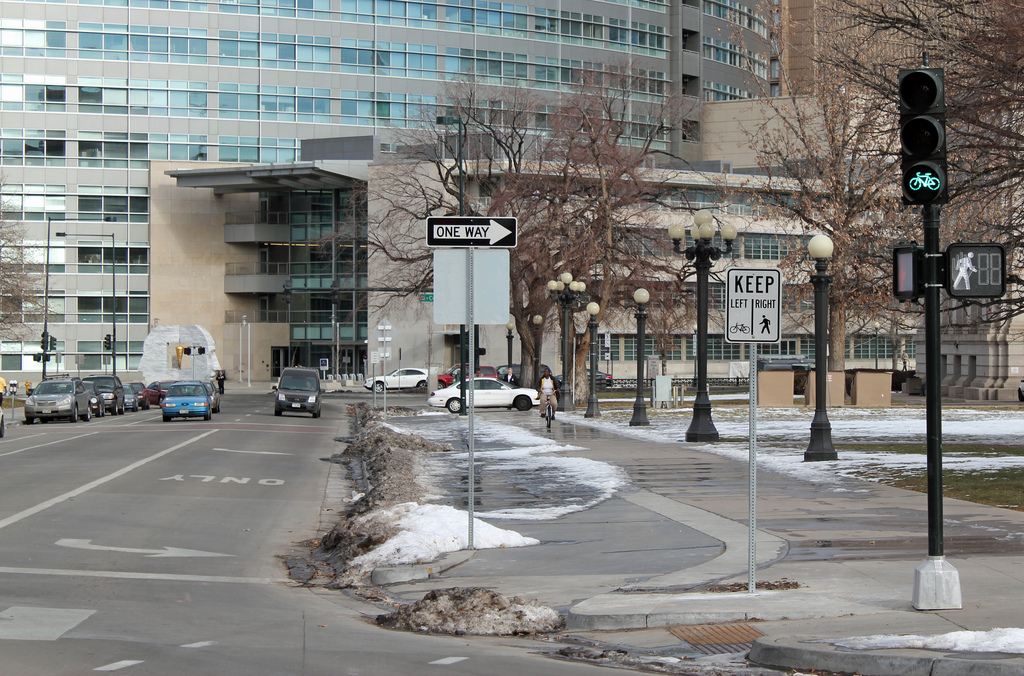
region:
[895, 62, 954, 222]
Stop sign attached to pole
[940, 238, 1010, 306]
Walk indicator sign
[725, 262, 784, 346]
White street sign with black lettering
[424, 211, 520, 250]
One way street sign attached to pole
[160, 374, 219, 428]
Blue car driving on road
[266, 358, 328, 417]
Black van in turn lane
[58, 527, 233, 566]
White painted arrow on road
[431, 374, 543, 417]
White car on road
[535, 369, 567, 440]
Person riding bike on sidewalk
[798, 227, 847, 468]
Street lamp on sidewalk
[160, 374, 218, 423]
Greenish blue small car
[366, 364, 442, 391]
Medium sized white vehicle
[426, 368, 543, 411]
Medium sized white vehicle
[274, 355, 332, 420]
Black sport utility vehicle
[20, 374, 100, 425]
Bronze sport utility vehicle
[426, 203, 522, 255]
Black and white sign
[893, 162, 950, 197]
Tiny green bicycle light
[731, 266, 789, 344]
Black and white sign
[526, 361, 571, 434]
Person riding a bicycle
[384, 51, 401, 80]
a window on a building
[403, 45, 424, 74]
a window on a building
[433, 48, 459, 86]
a window on a building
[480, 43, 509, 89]
a window on a building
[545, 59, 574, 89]
a window on a building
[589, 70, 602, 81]
a window on a building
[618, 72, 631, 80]
a window on a building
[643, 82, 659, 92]
a window on a building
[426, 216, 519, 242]
a "One Way" sign on a divider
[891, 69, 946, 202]
a traffic light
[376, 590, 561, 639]
a pile of dirty snow on the curb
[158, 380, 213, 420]
a blue car driving on the street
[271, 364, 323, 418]
a black van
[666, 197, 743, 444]
a street light on the sidewalk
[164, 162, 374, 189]
metal awning over a door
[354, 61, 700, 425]
a naked tree near the curb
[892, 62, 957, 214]
Stop light on pole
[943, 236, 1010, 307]
Walk signal on sign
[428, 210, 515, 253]
One way street sign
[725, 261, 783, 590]
Street sign on pole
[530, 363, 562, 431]
Person biking on sidewalk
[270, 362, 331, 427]
Black van driving in turn lane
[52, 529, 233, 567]
Painted arrow in street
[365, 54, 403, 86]
a window on the building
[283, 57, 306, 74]
a window on the building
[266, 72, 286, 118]
a window on the building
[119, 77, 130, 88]
a window on the building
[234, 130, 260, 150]
a window on the building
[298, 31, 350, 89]
a window on the building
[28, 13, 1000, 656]
street and sidewalk in front of large city building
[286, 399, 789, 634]
dirty slush and melting snow between street and sidewalk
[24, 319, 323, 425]
statue of two profiles in back of parked and moving cars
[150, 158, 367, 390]
roofed and terraced entryway into building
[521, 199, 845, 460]
black poles with white globes of light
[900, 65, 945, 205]
traffic signal showing lit green bicycle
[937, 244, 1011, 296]
traffic signal showing walking figure in white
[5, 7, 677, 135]
rows of window panes on curved building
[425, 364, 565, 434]
bicyclist riding in front of white car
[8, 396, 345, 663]
white lines, arrow and print on street surface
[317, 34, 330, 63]
building has a window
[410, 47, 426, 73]
building has a window